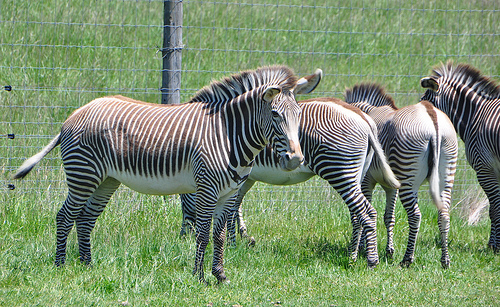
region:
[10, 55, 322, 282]
zebra standing in field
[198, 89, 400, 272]
zebra standing in field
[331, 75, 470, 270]
zebra standing in field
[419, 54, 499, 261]
zebra standing in field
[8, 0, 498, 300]
green grassy field with zebras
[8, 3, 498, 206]
barbed wire fence with wooden posts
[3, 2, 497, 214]
wood and metal fence surrounding zebras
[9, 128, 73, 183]
zebra tail extended out over grass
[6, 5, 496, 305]
sunny daytime zoo scene with animals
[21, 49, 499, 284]
black and white zebras in zoo setting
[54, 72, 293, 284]
black and white striped zebra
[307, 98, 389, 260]
black and white striped zebra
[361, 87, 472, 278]
black and white striped zebra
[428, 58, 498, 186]
black and white striped zebra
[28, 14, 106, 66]
long green and brown grass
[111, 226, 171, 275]
long green and brown grass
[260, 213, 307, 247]
long green and brown grass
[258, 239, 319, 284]
long green and brown grass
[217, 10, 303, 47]
long green and brown grass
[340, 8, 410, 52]
long green and brown grass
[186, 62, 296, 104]
Black and white zebra mane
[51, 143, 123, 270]
Back two legs of a zebra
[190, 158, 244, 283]
Front two legs of a zebra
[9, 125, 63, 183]
Tail of a zebra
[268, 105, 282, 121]
Right eye of a zebra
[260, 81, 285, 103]
Right ear of a zebra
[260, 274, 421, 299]
Bright green grassy field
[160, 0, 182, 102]
Wire attached to a wooden pole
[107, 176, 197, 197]
White belly of a zebra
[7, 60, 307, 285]
Black and white zebra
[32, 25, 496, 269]
four black and white zebras standing in a field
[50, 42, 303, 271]
black and white zebra standing in a field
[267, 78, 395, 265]
black and white zebra standing in a field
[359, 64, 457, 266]
black and white zebra standing in a field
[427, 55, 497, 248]
black and white zebra standing in a field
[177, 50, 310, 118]
mane of a black and white zebra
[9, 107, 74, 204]
tail of a black and white zebra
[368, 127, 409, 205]
tail of a black and white zebra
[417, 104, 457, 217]
tail of a black and white zebra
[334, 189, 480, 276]
legs of a zebras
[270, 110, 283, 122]
Eye of striped zebra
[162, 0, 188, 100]
Post for fence enclousure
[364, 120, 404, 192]
Tail of striped zebra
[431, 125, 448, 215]
Tail of striped zebra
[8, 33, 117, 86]
part of Wire fence for zebra enclousure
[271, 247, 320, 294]
Green grassy zebra area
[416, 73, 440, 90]
Ear of striped zebra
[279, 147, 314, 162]
Nose of striped zebra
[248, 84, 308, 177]
Head of striped zebra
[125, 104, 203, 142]
Back of striped zebra